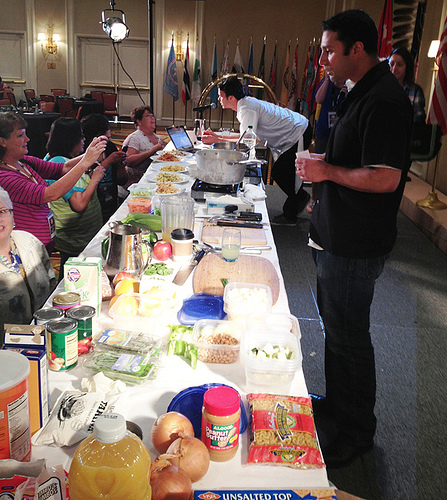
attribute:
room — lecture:
[4, 3, 446, 488]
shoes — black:
[312, 398, 376, 467]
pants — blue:
[312, 243, 389, 438]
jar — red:
[203, 385, 242, 462]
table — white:
[1, 131, 330, 499]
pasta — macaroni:
[246, 393, 323, 470]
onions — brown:
[151, 410, 209, 499]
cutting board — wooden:
[192, 251, 280, 306]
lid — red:
[204, 386, 242, 416]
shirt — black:
[305, 60, 413, 254]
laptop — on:
[166, 125, 201, 154]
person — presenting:
[217, 76, 314, 225]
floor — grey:
[261, 162, 446, 499]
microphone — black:
[193, 103, 216, 134]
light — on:
[104, 17, 129, 43]